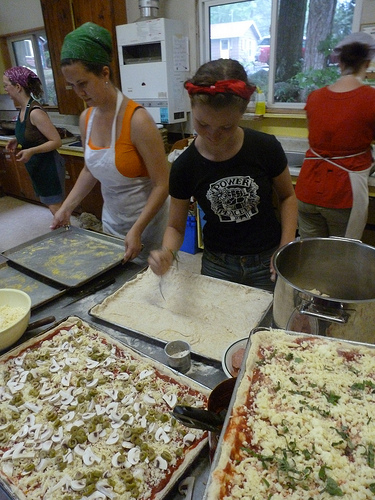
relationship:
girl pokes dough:
[147, 57, 299, 287] [92, 261, 282, 371]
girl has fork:
[147, 57, 299, 287] [156, 274, 168, 310]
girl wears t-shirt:
[147, 57, 299, 287] [171, 133, 288, 254]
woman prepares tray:
[47, 23, 171, 259] [12, 218, 133, 290]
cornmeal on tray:
[37, 235, 113, 279] [12, 218, 133, 290]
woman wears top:
[293, 35, 373, 247] [298, 86, 374, 211]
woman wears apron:
[47, 23, 171, 259] [77, 104, 165, 240]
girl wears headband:
[147, 57, 299, 287] [182, 75, 255, 98]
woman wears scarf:
[47, 23, 171, 259] [58, 23, 114, 70]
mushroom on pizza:
[90, 345, 105, 363] [1, 320, 220, 499]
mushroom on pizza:
[69, 425, 86, 444] [1, 320, 220, 499]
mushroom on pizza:
[73, 477, 98, 495] [1, 320, 220, 499]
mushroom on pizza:
[154, 406, 165, 424] [1, 320, 220, 499]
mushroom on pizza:
[140, 442, 152, 464] [1, 320, 220, 499]